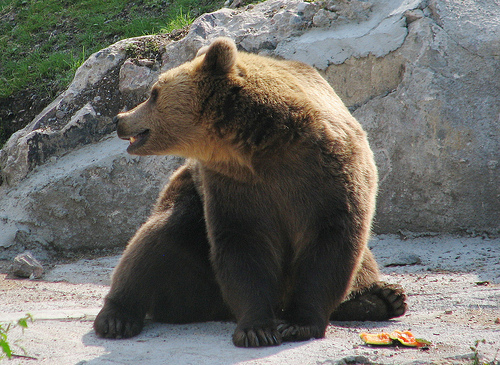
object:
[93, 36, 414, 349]
bear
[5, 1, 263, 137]
grass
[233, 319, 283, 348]
claw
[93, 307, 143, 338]
claw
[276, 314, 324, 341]
claw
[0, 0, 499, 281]
rock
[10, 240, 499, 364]
ground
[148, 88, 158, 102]
ear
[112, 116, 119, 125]
nose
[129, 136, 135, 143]
tooth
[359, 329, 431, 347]
food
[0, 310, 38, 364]
green leaves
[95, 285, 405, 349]
paws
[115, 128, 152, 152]
mouth